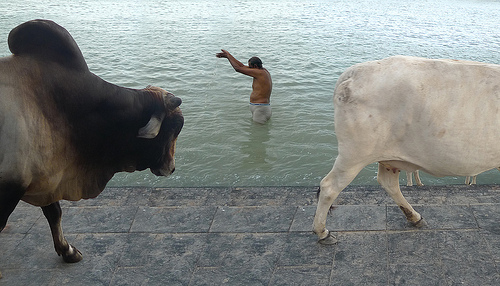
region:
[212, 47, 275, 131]
man wearing underwear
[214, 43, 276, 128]
man standing in a lake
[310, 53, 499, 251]
fat white cow walking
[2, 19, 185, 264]
black and brown animal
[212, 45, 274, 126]
man preparing to dive into water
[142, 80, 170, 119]
parted brown hair on top of head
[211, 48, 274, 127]
man wearing no shirt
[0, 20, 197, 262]
A black bull.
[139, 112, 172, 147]
The black bull's ear.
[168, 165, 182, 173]
The black bull's nose.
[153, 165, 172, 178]
The black bull's mouth.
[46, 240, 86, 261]
The black bull's hoof.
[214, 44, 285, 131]
The man in the water.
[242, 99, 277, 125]
The man has on swim trunks.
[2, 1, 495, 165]
The large body of water.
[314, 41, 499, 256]
The white bull.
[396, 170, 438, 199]
The white bull's udders.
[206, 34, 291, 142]
Man in the water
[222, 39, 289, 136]
Man wearing white underware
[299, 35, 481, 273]
White animal by the water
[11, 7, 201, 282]
Black animal by the water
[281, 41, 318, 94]
Small ripples in the water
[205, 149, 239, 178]
Small ripples in the water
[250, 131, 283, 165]
Small ripples in the water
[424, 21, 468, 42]
Small ripples in the water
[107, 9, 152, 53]
Small ripples in the water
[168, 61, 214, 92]
Small ripples in the water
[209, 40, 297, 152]
A man is in the water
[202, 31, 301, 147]
A man is in a large body of water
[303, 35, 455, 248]
The rear of an animal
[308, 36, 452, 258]
The rear of a white animal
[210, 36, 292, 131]
A man doesn't have his shirt on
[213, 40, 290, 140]
The person is missing a shirt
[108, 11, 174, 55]
A large body of water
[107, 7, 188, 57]
A large body of blue water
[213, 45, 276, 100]
The man's arms are extended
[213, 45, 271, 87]
The man's hands are open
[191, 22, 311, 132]
man in the water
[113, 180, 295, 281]
ground under the animals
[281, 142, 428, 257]
back legs of animal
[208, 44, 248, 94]
arms of the man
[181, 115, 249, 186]
water under the man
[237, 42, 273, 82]
head of the man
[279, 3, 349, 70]
water in the distance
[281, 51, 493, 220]
white animal in photo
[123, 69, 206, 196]
head of an animal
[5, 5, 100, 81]
hump on animal's back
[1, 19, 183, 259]
the cow is standing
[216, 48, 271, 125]
man in the water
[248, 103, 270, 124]
man is wearing underwear